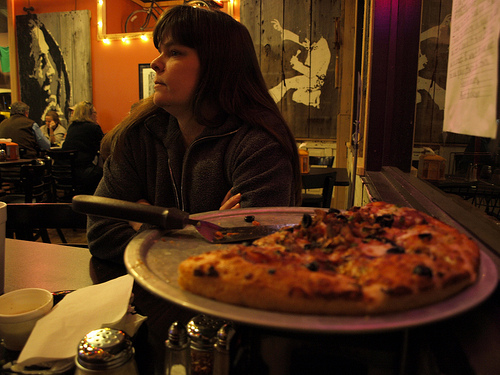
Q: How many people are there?
A: One.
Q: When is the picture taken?
A: Night time.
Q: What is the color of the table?
A: Brown.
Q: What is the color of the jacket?
A: Black.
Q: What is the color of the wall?
A: Orange.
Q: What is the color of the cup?
A: White.